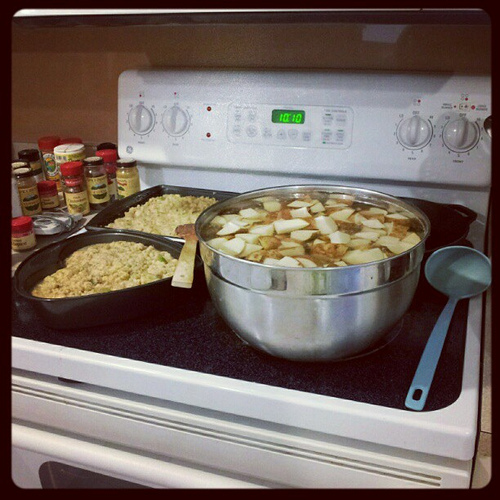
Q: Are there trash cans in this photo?
A: No, there are no trash cans.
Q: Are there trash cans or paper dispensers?
A: No, there are no trash cans or paper dispensers.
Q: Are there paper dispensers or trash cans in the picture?
A: No, there are no trash cans or paper dispensers.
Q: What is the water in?
A: The water is in the bowl.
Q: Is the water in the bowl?
A: Yes, the water is in the bowl.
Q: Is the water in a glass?
A: No, the water is in the bowl.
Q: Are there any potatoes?
A: Yes, there are potatoes.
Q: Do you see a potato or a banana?
A: Yes, there are potatoes.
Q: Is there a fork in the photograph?
A: No, there are no forks.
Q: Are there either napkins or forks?
A: No, there are no forks or napkins.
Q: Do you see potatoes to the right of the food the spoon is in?
A: Yes, there are potatoes to the right of the food.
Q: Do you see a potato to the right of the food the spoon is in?
A: Yes, there are potatoes to the right of the food.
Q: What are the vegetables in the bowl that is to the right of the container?
A: The vegetables are potatoes.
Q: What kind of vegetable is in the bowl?
A: The vegetables are potatoes.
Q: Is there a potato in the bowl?
A: Yes, there are potatoes in the bowl.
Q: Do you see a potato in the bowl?
A: Yes, there are potatoes in the bowl.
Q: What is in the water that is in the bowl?
A: The potatoes are in the water.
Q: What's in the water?
A: The potatoes are in the water.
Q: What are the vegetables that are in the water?
A: The vegetables are potatoes.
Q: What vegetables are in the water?
A: The vegetables are potatoes.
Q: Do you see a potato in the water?
A: Yes, there are potatoes in the water.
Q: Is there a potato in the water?
A: Yes, there are potatoes in the water.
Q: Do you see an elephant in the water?
A: No, there are potatoes in the water.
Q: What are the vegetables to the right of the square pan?
A: The vegetables are potatoes.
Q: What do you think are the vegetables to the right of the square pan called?
A: The vegetables are potatoes.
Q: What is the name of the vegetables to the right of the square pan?
A: The vegetables are potatoes.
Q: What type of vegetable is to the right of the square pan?
A: The vegetables are potatoes.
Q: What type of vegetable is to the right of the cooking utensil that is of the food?
A: The vegetables are potatoes.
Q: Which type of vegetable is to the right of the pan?
A: The vegetables are potatoes.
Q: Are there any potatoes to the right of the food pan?
A: Yes, there are potatoes to the right of the pan.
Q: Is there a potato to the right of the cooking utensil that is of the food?
A: Yes, there are potatoes to the right of the pan.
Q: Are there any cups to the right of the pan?
A: No, there are potatoes to the right of the pan.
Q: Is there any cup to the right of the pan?
A: No, there are potatoes to the right of the pan.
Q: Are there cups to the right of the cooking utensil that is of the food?
A: No, there are potatoes to the right of the pan.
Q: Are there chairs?
A: No, there are no chairs.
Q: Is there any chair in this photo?
A: No, there are no chairs.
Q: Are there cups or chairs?
A: No, there are no chairs or cups.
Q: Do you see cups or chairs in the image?
A: No, there are no chairs or cups.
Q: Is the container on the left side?
A: Yes, the container is on the left of the image.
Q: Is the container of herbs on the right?
A: No, the container is on the left of the image.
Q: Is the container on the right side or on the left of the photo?
A: The container is on the left of the image.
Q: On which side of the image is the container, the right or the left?
A: The container is on the left of the image.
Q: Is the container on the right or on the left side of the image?
A: The container is on the left of the image.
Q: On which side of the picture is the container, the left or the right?
A: The container is on the left of the image.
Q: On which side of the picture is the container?
A: The container is on the left of the image.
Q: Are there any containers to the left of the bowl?
A: Yes, there is a container to the left of the bowl.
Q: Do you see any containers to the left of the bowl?
A: Yes, there is a container to the left of the bowl.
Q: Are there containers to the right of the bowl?
A: No, the container is to the left of the bowl.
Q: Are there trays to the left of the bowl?
A: No, there is a container to the left of the bowl.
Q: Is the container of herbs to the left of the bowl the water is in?
A: Yes, the container is to the left of the bowl.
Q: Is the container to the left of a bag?
A: No, the container is to the left of the bowl.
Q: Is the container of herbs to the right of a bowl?
A: No, the container is to the left of a bowl.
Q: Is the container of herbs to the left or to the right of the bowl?
A: The container is to the left of the bowl.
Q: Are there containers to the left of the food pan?
A: Yes, there is a container to the left of the pan.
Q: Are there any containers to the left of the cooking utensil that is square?
A: Yes, there is a container to the left of the pan.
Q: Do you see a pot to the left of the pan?
A: No, there is a container to the left of the pan.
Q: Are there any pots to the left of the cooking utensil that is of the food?
A: No, there is a container to the left of the pan.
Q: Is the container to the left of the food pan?
A: Yes, the container is to the left of the pan.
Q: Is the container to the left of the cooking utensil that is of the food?
A: Yes, the container is to the left of the pan.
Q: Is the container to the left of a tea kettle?
A: No, the container is to the left of the pan.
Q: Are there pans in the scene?
A: Yes, there is a pan.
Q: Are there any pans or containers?
A: Yes, there is a pan.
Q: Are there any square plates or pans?
A: Yes, there is a square pan.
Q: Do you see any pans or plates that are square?
A: Yes, the pan is square.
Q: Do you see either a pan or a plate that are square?
A: Yes, the pan is square.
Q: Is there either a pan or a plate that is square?
A: Yes, the pan is square.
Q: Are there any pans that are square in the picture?
A: Yes, there is a square pan.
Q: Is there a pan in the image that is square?
A: Yes, there is a pan that is square.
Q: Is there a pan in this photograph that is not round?
A: Yes, there is a square pan.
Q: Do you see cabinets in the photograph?
A: No, there are no cabinets.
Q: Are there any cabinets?
A: No, there are no cabinets.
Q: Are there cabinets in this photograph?
A: No, there are no cabinets.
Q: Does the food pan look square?
A: Yes, the pan is square.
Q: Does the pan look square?
A: Yes, the pan is square.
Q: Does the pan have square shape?
A: Yes, the pan is square.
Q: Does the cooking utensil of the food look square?
A: Yes, the pan is square.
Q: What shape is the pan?
A: The pan is square.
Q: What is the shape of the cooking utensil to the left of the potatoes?
A: The pan is square.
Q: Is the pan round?
A: No, the pan is square.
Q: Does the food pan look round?
A: No, the pan is square.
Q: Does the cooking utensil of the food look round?
A: No, the pan is square.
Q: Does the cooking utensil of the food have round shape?
A: No, the pan is square.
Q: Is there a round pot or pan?
A: No, there is a pan but it is square.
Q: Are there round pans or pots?
A: No, there is a pan but it is square.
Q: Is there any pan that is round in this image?
A: No, there is a pan but it is square.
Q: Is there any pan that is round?
A: No, there is a pan but it is square.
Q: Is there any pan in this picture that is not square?
A: No, there is a pan but it is square.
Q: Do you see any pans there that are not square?
A: No, there is a pan but it is square.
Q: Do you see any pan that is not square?
A: No, there is a pan but it is square.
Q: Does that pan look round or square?
A: The pan is square.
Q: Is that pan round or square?
A: The pan is square.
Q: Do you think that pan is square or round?
A: The pan is square.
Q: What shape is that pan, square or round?
A: The pan is square.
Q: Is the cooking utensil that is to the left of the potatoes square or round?
A: The pan is square.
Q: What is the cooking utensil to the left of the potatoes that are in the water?
A: The cooking utensil is a pan.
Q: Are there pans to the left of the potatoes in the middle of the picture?
A: Yes, there is a pan to the left of the potatoes.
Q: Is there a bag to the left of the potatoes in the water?
A: No, there is a pan to the left of the potatoes.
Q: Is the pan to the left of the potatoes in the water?
A: Yes, the pan is to the left of the potatoes.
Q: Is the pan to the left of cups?
A: No, the pan is to the left of the potatoes.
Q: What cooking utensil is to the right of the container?
A: The cooking utensil is a pan.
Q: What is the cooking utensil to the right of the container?
A: The cooking utensil is a pan.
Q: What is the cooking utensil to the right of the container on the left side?
A: The cooking utensil is a pan.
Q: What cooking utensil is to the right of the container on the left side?
A: The cooking utensil is a pan.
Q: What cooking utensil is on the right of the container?
A: The cooking utensil is a pan.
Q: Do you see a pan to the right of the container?
A: Yes, there is a pan to the right of the container.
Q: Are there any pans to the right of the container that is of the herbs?
A: Yes, there is a pan to the right of the container.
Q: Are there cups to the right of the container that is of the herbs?
A: No, there is a pan to the right of the container.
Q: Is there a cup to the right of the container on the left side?
A: No, there is a pan to the right of the container.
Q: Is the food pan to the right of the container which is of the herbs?
A: Yes, the pan is to the right of the container.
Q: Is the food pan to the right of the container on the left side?
A: Yes, the pan is to the right of the container.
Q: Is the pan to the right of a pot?
A: No, the pan is to the right of the container.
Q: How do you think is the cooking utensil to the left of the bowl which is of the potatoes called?
A: The cooking utensil is a pan.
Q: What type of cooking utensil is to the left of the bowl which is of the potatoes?
A: The cooking utensil is a pan.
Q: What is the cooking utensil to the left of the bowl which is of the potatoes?
A: The cooking utensil is a pan.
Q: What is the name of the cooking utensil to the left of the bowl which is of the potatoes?
A: The cooking utensil is a pan.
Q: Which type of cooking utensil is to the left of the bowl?
A: The cooking utensil is a pan.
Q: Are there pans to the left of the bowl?
A: Yes, there is a pan to the left of the bowl.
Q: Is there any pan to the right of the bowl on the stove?
A: No, the pan is to the left of the bowl.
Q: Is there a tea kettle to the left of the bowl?
A: No, there is a pan to the left of the bowl.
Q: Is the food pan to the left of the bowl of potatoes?
A: Yes, the pan is to the left of the bowl.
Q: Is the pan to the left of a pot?
A: No, the pan is to the left of the bowl.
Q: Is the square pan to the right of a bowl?
A: No, the pan is to the left of a bowl.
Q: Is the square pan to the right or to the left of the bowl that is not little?
A: The pan is to the left of the bowl.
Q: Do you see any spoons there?
A: Yes, there is a spoon.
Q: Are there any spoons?
A: Yes, there is a spoon.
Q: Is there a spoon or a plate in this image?
A: Yes, there is a spoon.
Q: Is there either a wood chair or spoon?
A: Yes, there is a wood spoon.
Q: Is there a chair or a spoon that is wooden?
A: Yes, the spoon is wooden.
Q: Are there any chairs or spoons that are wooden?
A: Yes, the spoon is wooden.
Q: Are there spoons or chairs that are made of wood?
A: Yes, the spoon is made of wood.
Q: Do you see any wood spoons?
A: Yes, there is a wood spoon.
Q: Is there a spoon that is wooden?
A: Yes, there is a spoon that is wooden.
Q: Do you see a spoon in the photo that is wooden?
A: Yes, there is a spoon that is wooden.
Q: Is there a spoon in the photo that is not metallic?
A: Yes, there is a wooden spoon.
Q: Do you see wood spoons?
A: Yes, there is a spoon that is made of wood.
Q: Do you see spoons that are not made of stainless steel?
A: Yes, there is a spoon that is made of wood.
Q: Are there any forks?
A: No, there are no forks.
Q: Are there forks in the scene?
A: No, there are no forks.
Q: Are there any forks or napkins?
A: No, there are no forks or napkins.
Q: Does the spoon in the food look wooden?
A: Yes, the spoon is wooden.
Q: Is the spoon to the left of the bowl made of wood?
A: Yes, the spoon is made of wood.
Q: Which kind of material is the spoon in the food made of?
A: The spoon is made of wood.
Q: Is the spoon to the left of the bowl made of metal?
A: No, the spoon is made of wood.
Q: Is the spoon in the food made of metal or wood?
A: The spoon is made of wood.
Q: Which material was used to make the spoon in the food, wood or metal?
A: The spoon is made of wood.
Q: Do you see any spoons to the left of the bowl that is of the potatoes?
A: Yes, there is a spoon to the left of the bowl.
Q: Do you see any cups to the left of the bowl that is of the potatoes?
A: No, there is a spoon to the left of the bowl.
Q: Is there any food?
A: Yes, there is food.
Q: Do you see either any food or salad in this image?
A: Yes, there is food.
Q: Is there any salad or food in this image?
A: Yes, there is food.